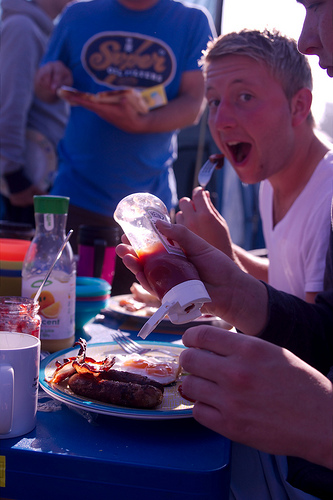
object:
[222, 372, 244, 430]
spots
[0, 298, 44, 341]
red jelly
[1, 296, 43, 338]
jam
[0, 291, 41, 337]
jar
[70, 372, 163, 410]
meal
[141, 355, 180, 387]
eggs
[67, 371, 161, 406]
brown sausage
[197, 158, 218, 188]
fork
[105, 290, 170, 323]
plate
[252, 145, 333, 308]
shirt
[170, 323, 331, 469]
hand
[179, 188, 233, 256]
hand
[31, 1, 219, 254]
man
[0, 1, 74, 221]
man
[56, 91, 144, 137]
hand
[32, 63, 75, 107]
hand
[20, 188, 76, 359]
bottle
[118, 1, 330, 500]
person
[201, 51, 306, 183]
face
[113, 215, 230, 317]
hand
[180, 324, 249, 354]
fingers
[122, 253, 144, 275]
fingers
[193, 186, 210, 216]
fingers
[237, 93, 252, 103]
eyes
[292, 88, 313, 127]
ear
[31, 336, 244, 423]
plate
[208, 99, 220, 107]
eye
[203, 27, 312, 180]
head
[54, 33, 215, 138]
arm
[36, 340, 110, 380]
bacon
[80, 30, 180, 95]
logo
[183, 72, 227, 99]
wall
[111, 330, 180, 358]
fork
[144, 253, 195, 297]
red ketchup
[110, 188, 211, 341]
plastic bottle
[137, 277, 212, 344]
lid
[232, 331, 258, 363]
knuckles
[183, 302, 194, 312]
ketchup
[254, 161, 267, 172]
spot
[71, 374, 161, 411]
sausage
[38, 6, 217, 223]
shirt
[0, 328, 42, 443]
coffee mug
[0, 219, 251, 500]
table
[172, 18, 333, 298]
man